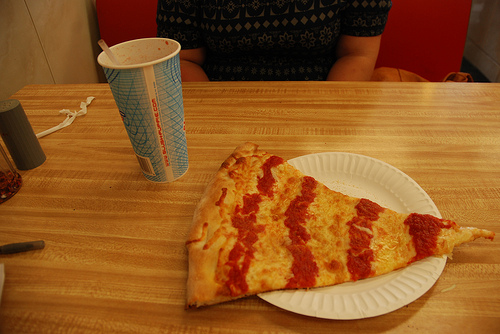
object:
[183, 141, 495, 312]
pizza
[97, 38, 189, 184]
cup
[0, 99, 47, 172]
pepper shaker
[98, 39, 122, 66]
straw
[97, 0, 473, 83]
bench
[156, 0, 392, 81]
woman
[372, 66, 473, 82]
bag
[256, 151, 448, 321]
plate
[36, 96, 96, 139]
straw paper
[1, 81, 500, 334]
table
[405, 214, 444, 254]
sauce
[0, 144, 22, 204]
pepper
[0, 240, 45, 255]
pen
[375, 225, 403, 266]
cheese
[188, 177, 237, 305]
crust